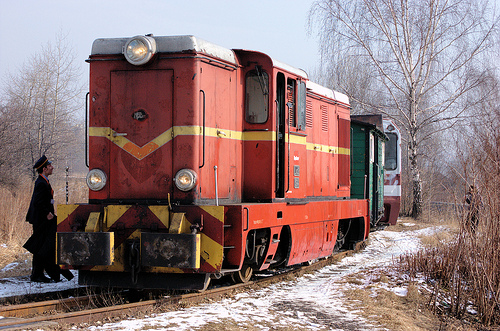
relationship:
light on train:
[117, 32, 184, 76] [93, 73, 177, 192]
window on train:
[242, 75, 313, 114] [93, 73, 177, 192]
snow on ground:
[274, 267, 347, 310] [301, 258, 442, 326]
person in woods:
[454, 188, 494, 232] [416, 104, 491, 240]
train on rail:
[93, 73, 177, 192] [1, 250, 369, 328]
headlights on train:
[173, 169, 199, 191] [93, 73, 177, 192]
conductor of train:
[25, 153, 86, 271] [93, 73, 177, 192]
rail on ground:
[1, 250, 369, 328] [301, 258, 442, 326]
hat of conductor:
[30, 145, 59, 174] [25, 153, 86, 271]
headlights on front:
[68, 145, 177, 192] [93, 69, 238, 254]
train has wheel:
[93, 73, 177, 192] [231, 243, 256, 269]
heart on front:
[111, 135, 194, 202] [93, 69, 238, 254]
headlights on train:
[68, 145, 177, 192] [93, 73, 177, 192]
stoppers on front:
[67, 219, 170, 301] [93, 69, 238, 254]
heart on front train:
[119, 137, 163, 191] [93, 73, 177, 192]